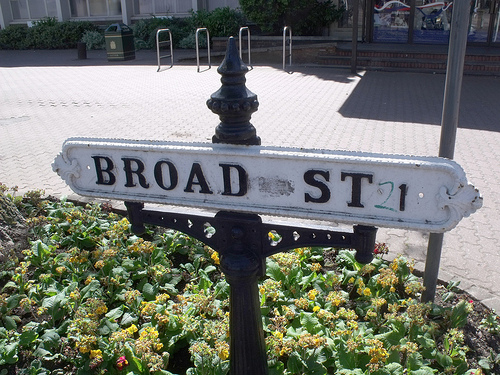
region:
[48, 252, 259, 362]
Flowers are yellow color.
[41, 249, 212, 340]
Leaves are green color.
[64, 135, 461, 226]
Board is black and white color.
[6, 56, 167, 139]
Pathway is grey color.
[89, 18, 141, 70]
Trash is green color.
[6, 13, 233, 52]
Plants are in sides of the wall.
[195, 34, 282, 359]
Pole is black color.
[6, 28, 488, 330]
Day time picture.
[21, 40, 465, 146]
Shadow falls on the pathway.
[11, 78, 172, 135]
Pathway is made of concrete bricks.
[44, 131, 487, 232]
a white and black street sign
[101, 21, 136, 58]
a trash can in front of a building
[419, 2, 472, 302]
a round metal pole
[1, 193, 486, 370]
a flower bed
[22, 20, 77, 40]
a bush in front of a building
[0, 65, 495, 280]
a brick paved drive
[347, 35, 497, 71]
steps going up to a building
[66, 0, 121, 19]
a window in a buildin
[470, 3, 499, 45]
the glass front door on a building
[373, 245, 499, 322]
a brick edging around a flower bed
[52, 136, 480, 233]
a white sign with black lettering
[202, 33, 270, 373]
a black metal sign post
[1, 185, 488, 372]
a bed of green and yellow flowers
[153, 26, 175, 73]
a bent metal post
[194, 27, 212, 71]
a bent metal post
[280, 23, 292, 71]
a bent metal post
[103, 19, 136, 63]
a green trash can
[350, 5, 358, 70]
a thin metal post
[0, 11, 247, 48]
a planter of shrubs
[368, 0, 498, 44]
glass windows on a building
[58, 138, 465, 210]
this is a side post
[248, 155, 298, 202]
the post is white in color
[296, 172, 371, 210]
the st is in black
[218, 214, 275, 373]
this is a pole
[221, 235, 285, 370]
the pole is black in color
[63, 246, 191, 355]
these are cactus planted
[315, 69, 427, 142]
this is a pavement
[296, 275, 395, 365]
the cactus are green in color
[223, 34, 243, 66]
the top[ is sharp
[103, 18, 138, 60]
this is a dustbin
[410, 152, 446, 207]
part of a board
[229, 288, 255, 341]
part fo a post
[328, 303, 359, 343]
part of a plant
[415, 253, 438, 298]
part of a poost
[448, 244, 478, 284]
part of a floor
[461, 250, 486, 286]
part of a floor